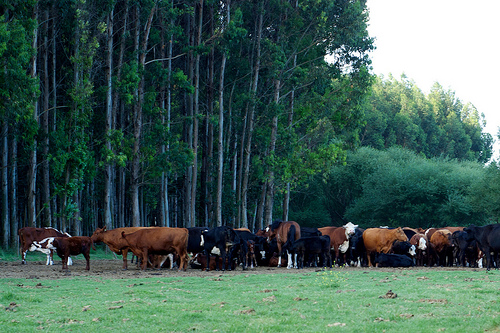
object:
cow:
[18, 222, 500, 272]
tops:
[0, 1, 377, 117]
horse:
[267, 220, 301, 269]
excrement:
[378, 290, 397, 299]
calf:
[29, 236, 73, 265]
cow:
[373, 252, 414, 267]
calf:
[46, 236, 97, 272]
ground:
[16, 260, 143, 279]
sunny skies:
[369, 0, 500, 74]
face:
[346, 222, 355, 232]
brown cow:
[19, 226, 188, 272]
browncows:
[363, 227, 409, 269]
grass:
[0, 270, 500, 333]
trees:
[37, 43, 318, 307]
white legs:
[286, 250, 298, 266]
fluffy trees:
[323, 144, 499, 229]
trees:
[0, 0, 378, 251]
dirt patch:
[0, 260, 500, 278]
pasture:
[0, 225, 500, 316]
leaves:
[318, 143, 347, 166]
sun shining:
[326, 0, 499, 167]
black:
[187, 226, 268, 271]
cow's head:
[343, 222, 359, 235]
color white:
[331, 221, 359, 253]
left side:
[6, 0, 175, 210]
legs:
[286, 249, 298, 265]